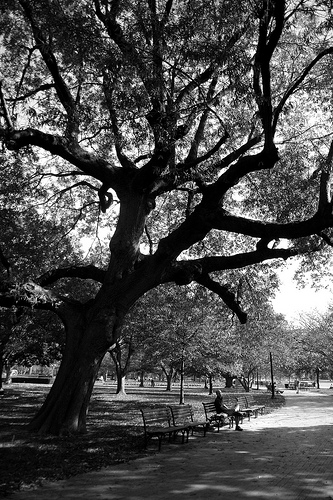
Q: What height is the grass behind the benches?
A: The grass is short.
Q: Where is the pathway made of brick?
A: In front of the benches.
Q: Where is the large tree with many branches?
A: Behind the benches.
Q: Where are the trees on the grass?
A: Behind the benches.and the brick road.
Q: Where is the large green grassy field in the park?
A: Behind the benches and next to the brick road.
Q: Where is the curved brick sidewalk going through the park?
A: Next to the grassy field.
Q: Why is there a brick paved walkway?
A: For people to walk on.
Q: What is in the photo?
A: Large tree.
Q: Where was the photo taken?
A: During the daytime.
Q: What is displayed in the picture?
A: Tree branches with scattered leaves.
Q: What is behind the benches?
A: Large tree.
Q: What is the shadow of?
A: Large tree.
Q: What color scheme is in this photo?
A: Black, White.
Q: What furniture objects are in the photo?
A: Benches.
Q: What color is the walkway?
A: Grey.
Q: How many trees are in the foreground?
A: One.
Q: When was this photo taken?
A: Daytime.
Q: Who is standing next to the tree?
A: No one.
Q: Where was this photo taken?
A: In a park.